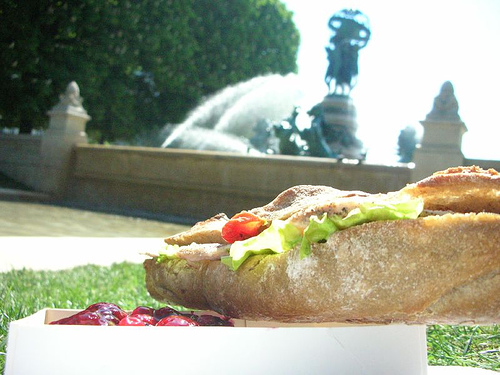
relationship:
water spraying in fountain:
[197, 82, 255, 150] [157, 32, 402, 207]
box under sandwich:
[12, 315, 436, 374] [139, 160, 499, 324]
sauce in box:
[47, 276, 229, 343] [7, 303, 428, 373]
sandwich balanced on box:
[130, 150, 499, 345] [4, 283, 452, 374]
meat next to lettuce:
[176, 240, 230, 263] [218, 195, 427, 272]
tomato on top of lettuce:
[221, 211, 264, 243] [211, 188, 423, 270]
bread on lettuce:
[142, 166, 500, 324] [218, 195, 427, 272]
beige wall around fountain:
[4, 138, 406, 227] [278, 0, 378, 167]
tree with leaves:
[1, 0, 298, 149] [6, 1, 299, 121]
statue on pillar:
[307, 0, 365, 100] [311, 97, 358, 157]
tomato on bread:
[221, 208, 266, 248] [142, 166, 500, 324]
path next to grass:
[0, 233, 174, 272] [0, 191, 199, 236]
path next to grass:
[0, 233, 174, 272] [0, 261, 497, 371]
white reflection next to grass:
[7, 197, 137, 271] [32, 275, 112, 294]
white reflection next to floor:
[7, 197, 137, 271] [2, 178, 202, 238]